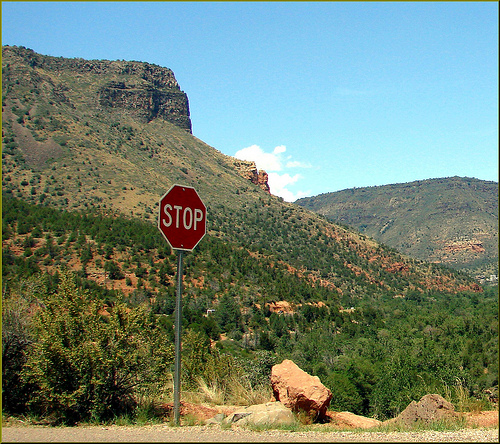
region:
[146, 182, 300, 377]
Stop sign is red.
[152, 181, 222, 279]
STOP is written in white letters.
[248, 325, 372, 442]
Big rock near stop sign.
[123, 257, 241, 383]
Stop sign connected to gray pole.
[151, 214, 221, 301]
Stop sign has 8 sides.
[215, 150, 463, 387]
Many green trees on mountain side.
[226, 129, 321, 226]
White clouds in sky.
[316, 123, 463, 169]
Sky is blue in color.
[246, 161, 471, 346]
Big mountains in background.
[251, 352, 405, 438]
Rocks are brown in color.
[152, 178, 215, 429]
a stop sign in the seemingly middle of nowhere.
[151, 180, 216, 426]
stop sign is angled towards its left [viewer's right] in the photo.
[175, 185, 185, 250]
two bolts hold the stop sign to its post.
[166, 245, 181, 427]
stop sign's post is silvertone metal, probably steel.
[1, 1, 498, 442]
photo is of some western state [calif, new mexico, arizona, etc & ect]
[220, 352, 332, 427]
large red rock leans on yellowish rock in foreground.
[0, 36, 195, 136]
primary mountain has a squarish, angular top.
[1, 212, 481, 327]
much of the mountain's earth is rusty red.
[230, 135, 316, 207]
a single cloud with two little stragglers between & behind two mountains.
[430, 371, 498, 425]
a few greenish yellow weeds right front.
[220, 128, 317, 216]
single white cloud in clear blue sky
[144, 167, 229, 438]
stop sign in dessert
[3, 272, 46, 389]
dead bush surrounded by green lush bushes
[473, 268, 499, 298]
buildings behind mountain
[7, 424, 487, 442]
shoulder of road in mountains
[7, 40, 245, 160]
mountain top with sharp cut off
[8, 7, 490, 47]
beautiful crystal clear blue skies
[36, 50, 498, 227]
mountains in background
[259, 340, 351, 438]
boulder sitting upright between two other boulders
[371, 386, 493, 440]
boulder stands alone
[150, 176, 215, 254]
A red stop sign.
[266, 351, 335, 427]
A large rock, protruding from the road.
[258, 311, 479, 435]
Brush amid the rocks.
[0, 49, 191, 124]
A hill looks out over the prairie.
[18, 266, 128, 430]
A large shrub near a sign.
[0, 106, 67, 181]
A patch of barren dirt on the hill.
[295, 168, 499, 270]
A barren hill in the distance.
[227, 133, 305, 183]
A single cloud overlooking the prairie.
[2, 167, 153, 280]
Small bushes dot the foot of the hill.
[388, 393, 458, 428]
A porous rock laying on the path.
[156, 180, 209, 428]
Stop sign on a post.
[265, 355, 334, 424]
Rock near stop sign.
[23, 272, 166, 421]
Bush near stop sign.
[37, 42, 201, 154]
Rocky mountain overlook into valley.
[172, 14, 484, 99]
Clear blue sky.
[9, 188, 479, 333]
Green vegetation growing on the mountain side.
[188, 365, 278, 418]
Dry, dead brush inbetween the rock and sign.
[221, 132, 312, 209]
Puffy white cloud in the sky.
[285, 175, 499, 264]
Mountain in the background.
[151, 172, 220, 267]
White and red stop sign.